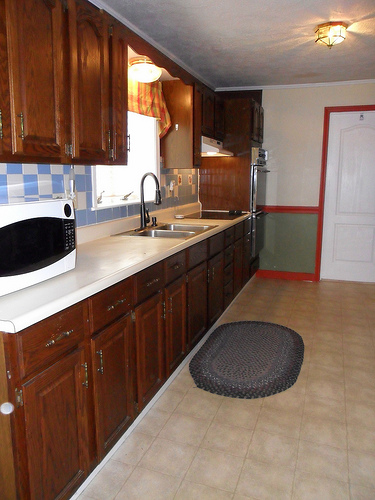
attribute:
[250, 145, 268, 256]
oven — stainless steel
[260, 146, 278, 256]
fridge — silver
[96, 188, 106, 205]
handle — crank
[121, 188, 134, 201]
handle — crank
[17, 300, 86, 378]
drawer — antique, brass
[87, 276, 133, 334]
drawer — antique, brass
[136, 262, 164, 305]
drawer — antique, brass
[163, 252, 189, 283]
drawer — antique, brass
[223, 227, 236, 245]
drawer — antique, brass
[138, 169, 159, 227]
faucet — Black 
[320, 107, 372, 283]
door — white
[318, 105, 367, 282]
door — white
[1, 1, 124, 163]
cabinet — brown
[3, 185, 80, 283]
microwave — white, black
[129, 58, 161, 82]
light — on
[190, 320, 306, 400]
mat — gray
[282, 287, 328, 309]
tile — white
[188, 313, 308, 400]
mat — grey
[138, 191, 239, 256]
sink — steel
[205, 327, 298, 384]
mat — grey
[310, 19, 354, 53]
light — on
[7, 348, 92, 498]
cabinet — wooden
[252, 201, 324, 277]
wall — green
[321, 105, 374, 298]
door — white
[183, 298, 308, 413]
rug — blue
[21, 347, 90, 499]
cabinet — wood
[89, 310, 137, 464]
cabinet — wood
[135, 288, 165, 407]
cabinet — wood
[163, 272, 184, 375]
cabinet — wood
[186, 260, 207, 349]
cabinet — wood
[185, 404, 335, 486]
pattern — tan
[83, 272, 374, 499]
floor — tiled